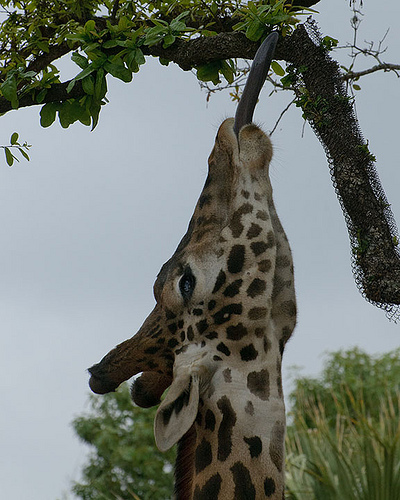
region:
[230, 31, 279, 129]
Giraffe tongue sticking out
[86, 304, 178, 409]
Horns on a giraffe's head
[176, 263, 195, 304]
Eye on a giraffe's head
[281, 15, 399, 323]
Wire mesh on a branch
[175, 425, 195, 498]
Brown hair on a giraffe's back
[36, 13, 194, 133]
green leaves on a tree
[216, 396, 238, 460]
Brown spot on a giraffe's neck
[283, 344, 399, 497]
Trees behind a giraffe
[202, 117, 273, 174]
Nose and mouth on a giraffe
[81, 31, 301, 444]
Giraffe eating leaves from a tree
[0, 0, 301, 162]
green leaves on branch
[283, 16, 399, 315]
wire mesh on tree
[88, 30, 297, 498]
giraffe with tongue out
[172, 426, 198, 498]
mane on back of neck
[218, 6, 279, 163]
long tongue reaching for leaf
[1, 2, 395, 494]
blue of daytime sky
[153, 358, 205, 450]
pointed ear of giraffe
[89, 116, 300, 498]
giraffe head pointed upward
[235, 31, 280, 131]
underside of giraffe tongue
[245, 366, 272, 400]
brown spot on fur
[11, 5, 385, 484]
Giraffe at a safari.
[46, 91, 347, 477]
Giraffe with beige fur and dark brown spots.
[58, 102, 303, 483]
Head and neck of a giraffe.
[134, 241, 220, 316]
Eye of a giraffe.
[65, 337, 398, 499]
Tall trees in a safari.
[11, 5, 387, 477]
Giraffe looking in the air towards a tree.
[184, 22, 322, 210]
Giraffe eating a large vegetable.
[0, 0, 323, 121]
Green leaves of a large tree branch.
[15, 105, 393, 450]
Clear blue sky at a safari.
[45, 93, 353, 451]
Head of a giraffe.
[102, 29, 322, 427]
a giraffe with a long tounge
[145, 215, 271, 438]
spots on a giraffe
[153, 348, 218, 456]
the ear of a giraffe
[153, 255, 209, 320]
the eye of a giraffe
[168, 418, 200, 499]
the mane on a giraffe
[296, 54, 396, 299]
a tree branch wrapped in netting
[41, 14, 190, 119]
leaves on a tree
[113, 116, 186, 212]
cloudless patch of sky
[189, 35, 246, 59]
the bark of a tree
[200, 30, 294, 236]
the mouth of a giraffe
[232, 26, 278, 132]
Black tongue of a giraffe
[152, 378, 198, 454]
Small gray ear of giraffe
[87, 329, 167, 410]
Short brown giraffe's horn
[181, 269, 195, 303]
Small eye of giraffe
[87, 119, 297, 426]
Extended head of giraffe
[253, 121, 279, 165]
Hair on giraffe's mouth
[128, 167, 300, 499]
Brown spots on giraffe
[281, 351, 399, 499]
Tall light green plants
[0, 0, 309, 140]
Leaves growing on a tree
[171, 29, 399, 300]
Black back of a tree